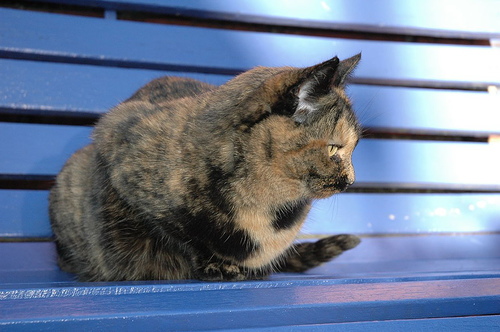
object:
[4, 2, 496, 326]
bench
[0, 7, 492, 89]
plank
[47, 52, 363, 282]
cat